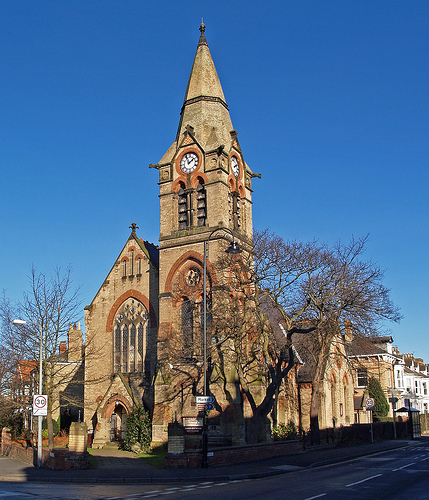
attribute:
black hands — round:
[185, 152, 196, 166]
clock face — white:
[179, 151, 201, 174]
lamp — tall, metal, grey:
[1, 313, 76, 450]